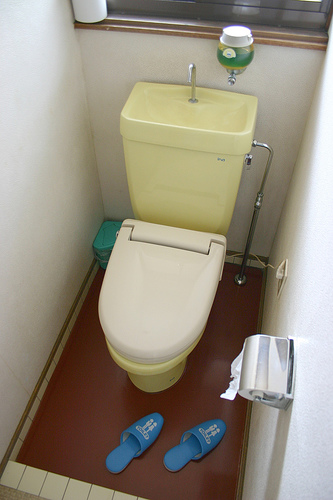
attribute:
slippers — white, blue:
[102, 411, 232, 475]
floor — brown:
[2, 374, 235, 500]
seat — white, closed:
[97, 219, 229, 366]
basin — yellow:
[114, 358, 191, 391]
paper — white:
[219, 344, 244, 414]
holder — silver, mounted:
[242, 332, 295, 406]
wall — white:
[293, 175, 325, 405]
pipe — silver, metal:
[235, 138, 281, 301]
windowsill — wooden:
[122, 13, 216, 38]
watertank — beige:
[118, 143, 247, 221]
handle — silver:
[242, 147, 254, 169]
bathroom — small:
[6, 5, 331, 495]